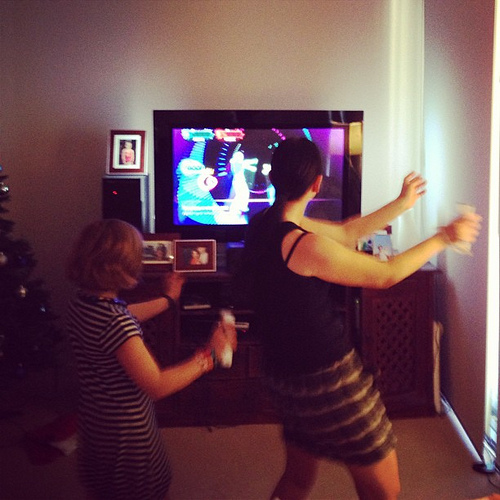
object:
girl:
[66, 217, 237, 497]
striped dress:
[62, 288, 172, 500]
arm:
[303, 199, 403, 243]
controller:
[216, 307, 234, 370]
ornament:
[19, 285, 27, 298]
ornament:
[39, 306, 46, 312]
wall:
[1, 1, 125, 118]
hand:
[401, 171, 428, 208]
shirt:
[240, 209, 354, 377]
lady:
[245, 138, 484, 499]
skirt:
[267, 349, 399, 466]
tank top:
[246, 210, 356, 370]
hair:
[66, 218, 145, 291]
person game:
[56, 219, 236, 497]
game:
[173, 128, 345, 228]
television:
[153, 109, 364, 243]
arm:
[278, 228, 448, 290]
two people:
[190, 246, 208, 265]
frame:
[172, 238, 218, 272]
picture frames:
[105, 129, 148, 175]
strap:
[434, 226, 454, 247]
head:
[269, 136, 324, 207]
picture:
[112, 134, 141, 169]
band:
[163, 300, 178, 312]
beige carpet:
[1, 412, 489, 498]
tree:
[0, 170, 67, 452]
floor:
[7, 360, 498, 497]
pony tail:
[254, 192, 289, 282]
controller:
[453, 203, 480, 255]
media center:
[72, 191, 454, 427]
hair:
[233, 136, 322, 333]